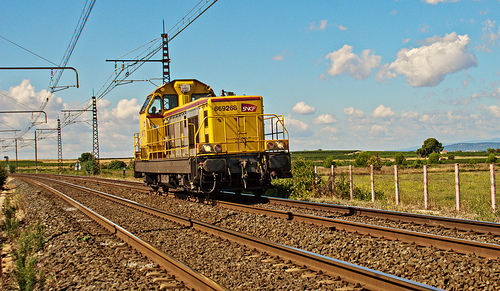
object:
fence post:
[347, 163, 354, 203]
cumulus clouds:
[319, 33, 478, 89]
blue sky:
[220, 4, 328, 84]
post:
[90, 94, 100, 171]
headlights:
[203, 144, 211, 153]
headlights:
[132, 79, 294, 196]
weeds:
[3, 203, 59, 287]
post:
[370, 163, 375, 201]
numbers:
[214, 104, 237, 110]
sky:
[1, 1, 498, 158]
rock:
[55, 230, 67, 239]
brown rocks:
[29, 180, 500, 291]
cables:
[3, 0, 225, 158]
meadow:
[317, 162, 500, 225]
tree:
[417, 138, 444, 166]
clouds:
[384, 30, 478, 87]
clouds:
[324, 45, 383, 80]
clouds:
[292, 100, 316, 115]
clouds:
[312, 113, 337, 125]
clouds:
[308, 16, 328, 30]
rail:
[20, 170, 500, 286]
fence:
[298, 155, 500, 213]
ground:
[19, 168, 489, 289]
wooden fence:
[303, 160, 498, 218]